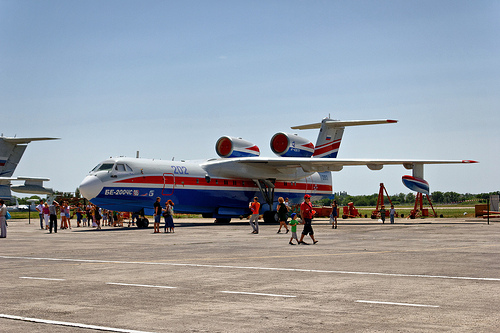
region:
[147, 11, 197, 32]
this is the sky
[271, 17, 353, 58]
the sky is blue in color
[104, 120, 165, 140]
the clouds are white in color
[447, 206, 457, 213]
this is the grass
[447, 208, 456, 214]
the grass is green in color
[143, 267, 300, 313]
this is the runway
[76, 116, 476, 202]
this is an airplane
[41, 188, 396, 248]
these are some people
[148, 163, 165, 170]
the airplane is grey in color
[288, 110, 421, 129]
top part of the plane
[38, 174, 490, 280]
group of peple stanindg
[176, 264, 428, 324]
white lines in the ground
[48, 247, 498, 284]
a straight white line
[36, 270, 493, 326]
a white dotted lines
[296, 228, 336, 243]
legs of the person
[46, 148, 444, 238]
a very big plane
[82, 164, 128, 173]
front window of the plane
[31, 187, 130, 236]
people standing infront of plane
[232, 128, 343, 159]
top part of the plane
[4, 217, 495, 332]
white marking strips on the ground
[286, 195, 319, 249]
a woman is walking with a kid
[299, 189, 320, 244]
a person is walking in red dress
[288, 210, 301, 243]
a kind is walking in green color dress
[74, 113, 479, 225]
an aircraft is parked in the ground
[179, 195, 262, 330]
a guy is walking on the ground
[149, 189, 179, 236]
a group of people standing together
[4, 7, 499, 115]
the sky is very clear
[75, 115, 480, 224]
the aircraft is painted with red, white and blue colors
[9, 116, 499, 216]
grass fields and bushes of trees are behind the aircraft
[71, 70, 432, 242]
plane on the ground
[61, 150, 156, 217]
front of the plane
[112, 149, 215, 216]
red, white and blue plane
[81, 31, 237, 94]
blue sky above the land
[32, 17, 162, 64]
sky with no clouds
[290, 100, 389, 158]
tail of the plane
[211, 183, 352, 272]
people on the ground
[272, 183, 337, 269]
adult and child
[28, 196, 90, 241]
people next to the plane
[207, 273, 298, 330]
white line on ground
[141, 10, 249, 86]
this is the sky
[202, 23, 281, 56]
the sky is blue in color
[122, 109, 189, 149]
the sky has clouds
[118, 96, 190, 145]
the clouds are white in color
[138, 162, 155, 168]
the airplane is grey in color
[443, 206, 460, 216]
this is the grass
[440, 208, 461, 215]
the grass is green in color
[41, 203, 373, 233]
these are some people